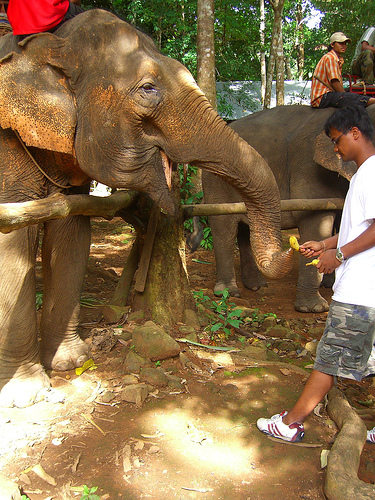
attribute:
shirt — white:
[329, 152, 374, 309]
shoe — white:
[256, 408, 307, 444]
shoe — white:
[363, 424, 374, 441]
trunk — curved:
[166, 84, 301, 281]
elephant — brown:
[1, 9, 315, 407]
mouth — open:
[153, 143, 193, 216]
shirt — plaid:
[309, 47, 346, 106]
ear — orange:
[0, 30, 77, 156]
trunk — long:
[172, 94, 296, 279]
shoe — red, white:
[254, 409, 304, 443]